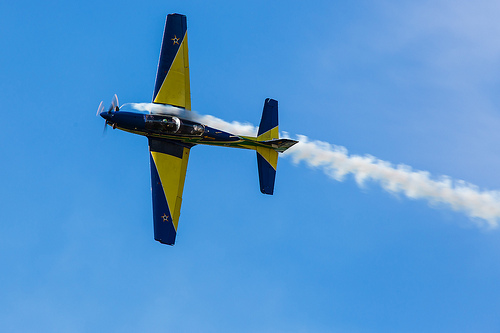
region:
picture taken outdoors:
[37, 35, 498, 250]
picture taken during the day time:
[37, 33, 499, 283]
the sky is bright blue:
[32, 41, 92, 295]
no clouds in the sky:
[60, 52, 492, 283]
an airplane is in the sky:
[57, 30, 432, 251]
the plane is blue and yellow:
[82, 30, 365, 223]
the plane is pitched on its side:
[89, 32, 349, 212]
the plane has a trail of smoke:
[194, 114, 464, 284]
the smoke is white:
[227, 77, 479, 218]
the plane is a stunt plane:
[104, 34, 338, 263]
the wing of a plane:
[147, 6, 193, 92]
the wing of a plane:
[141, 146, 192, 256]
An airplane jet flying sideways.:
[95, 10, 302, 248]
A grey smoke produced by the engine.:
[191, 103, 497, 228]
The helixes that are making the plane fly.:
[93, 90, 119, 140]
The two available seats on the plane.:
[141, 111, 203, 136]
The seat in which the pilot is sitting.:
[148, 115, 179, 135]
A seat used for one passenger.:
[177, 120, 205, 137]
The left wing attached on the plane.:
[145, 137, 190, 243]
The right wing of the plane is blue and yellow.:
[150, 10, 190, 110]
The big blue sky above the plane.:
[0, 0, 496, 328]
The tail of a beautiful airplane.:
[252, 96, 299, 194]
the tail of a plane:
[255, 90, 301, 198]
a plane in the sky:
[82, 6, 299, 247]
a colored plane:
[90, 2, 297, 247]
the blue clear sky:
[0, 0, 499, 328]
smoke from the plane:
[251, 110, 496, 245]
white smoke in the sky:
[310, 139, 363, 179]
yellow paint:
[161, 28, 191, 100]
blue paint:
[149, 172, 170, 242]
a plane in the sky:
[57, 2, 415, 312]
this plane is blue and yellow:
[73, 17, 338, 239]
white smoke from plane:
[75, 51, 393, 278]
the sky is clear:
[33, 177, 110, 252]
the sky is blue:
[16, 164, 138, 266]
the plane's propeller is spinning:
[91, 72, 155, 165]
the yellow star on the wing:
[132, 185, 225, 258]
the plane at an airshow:
[81, 16, 393, 281]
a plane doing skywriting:
[73, 49, 408, 307]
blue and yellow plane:
[60, 64, 358, 291]